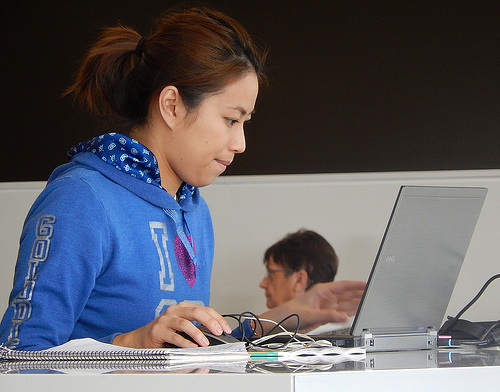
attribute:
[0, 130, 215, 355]
shirt — blue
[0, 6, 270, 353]
girl — viewing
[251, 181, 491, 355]
laptop — open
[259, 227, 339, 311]
person — behind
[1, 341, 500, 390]
table — white, silver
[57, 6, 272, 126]
hair — ponytail, brown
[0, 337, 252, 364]
notebook — spiral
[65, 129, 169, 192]
liner — blue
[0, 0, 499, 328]
wall — black, white